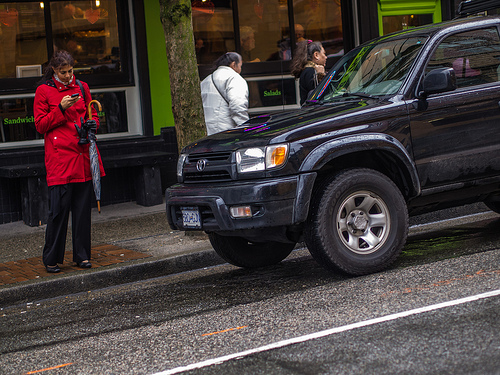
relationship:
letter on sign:
[184, 211, 195, 224] [180, 207, 202, 232]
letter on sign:
[268, 83, 285, 97] [204, 54, 307, 113]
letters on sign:
[4, 116, 35, 125] [0, 111, 32, 126]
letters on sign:
[4, 110, 34, 130] [4, 84, 145, 146]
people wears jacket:
[33, 50, 107, 273] [31, 77, 114, 187]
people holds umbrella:
[33, 50, 107, 273] [81, 91, 112, 216]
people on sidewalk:
[38, 52, 330, 92] [95, 215, 175, 260]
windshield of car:
[315, 32, 434, 104] [165, 16, 495, 280]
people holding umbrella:
[33, 50, 107, 273] [75, 97, 107, 217]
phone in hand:
[71, 93, 83, 103] [58, 90, 80, 112]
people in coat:
[33, 50, 107, 273] [30, 77, 107, 186]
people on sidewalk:
[33, 50, 107, 273] [5, 182, 212, 292]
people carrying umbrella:
[33, 50, 107, 273] [83, 98, 103, 216]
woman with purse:
[175, 50, 295, 140] [211, 87, 269, 131]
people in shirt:
[33, 50, 107, 273] [29, 83, 125, 182]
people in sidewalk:
[33, 50, 107, 273] [1, 205, 291, 297]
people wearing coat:
[33, 50, 107, 273] [31, 69, 112, 191]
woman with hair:
[295, 40, 328, 104] [293, 35, 323, 70]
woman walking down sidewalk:
[290, 39, 328, 106] [6, 202, 270, 289]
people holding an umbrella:
[33, 50, 107, 273] [68, 78, 123, 211]